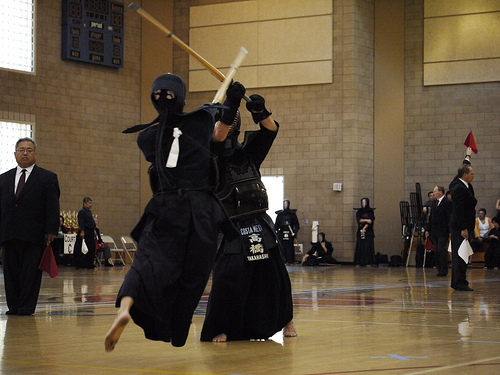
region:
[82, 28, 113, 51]
scoreboard on the wall.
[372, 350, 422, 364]
blue tape on the floor.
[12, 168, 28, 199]
tie on man's chest.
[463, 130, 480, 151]
red flag in man's hand.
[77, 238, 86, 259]
white flag in man's hand.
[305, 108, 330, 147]
wall made of blocks.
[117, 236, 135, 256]
chair on the floor.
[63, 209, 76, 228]
trophies on a table.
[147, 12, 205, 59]
staff in man's hand.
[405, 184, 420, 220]
metal gates near bleachers.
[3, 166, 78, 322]
the suit is black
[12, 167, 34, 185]
the shirt is white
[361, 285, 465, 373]
the floor is shiny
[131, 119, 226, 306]
the attire is black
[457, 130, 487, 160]
the clothe is red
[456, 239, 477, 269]
the clothe is white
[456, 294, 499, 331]
reflection is on the floor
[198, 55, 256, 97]
the swords are wooden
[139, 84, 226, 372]
the gloves are black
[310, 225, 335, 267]
the man is sitting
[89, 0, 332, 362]
two people in a martial arts fight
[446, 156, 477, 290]
a man holding a white cloth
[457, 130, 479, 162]
a hand holding a red cloth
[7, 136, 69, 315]
a man wearing a black suit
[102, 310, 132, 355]
a bare dirty foot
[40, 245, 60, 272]
a red cloth in a hand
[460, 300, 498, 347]
a reflection on the shiny floor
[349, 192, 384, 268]
a competitor waiting his turn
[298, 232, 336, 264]
a martial arts performer sitting on the floor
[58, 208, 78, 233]
golden trophies on a table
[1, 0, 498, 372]
people in a gym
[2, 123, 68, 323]
man wearing black suit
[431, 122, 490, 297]
man holding up a red hanky on left hand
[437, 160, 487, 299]
man holding a white hanky on right hand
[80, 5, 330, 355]
two men are fighting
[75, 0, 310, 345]
men are holding bats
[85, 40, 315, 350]
man wearing black uniforms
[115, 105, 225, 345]
a black tunica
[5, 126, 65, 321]
man wears a white shirt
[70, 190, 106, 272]
man holding a white hanky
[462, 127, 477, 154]
a raised red cloth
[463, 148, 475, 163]
black band of a wrist watch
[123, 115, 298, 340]
fighters wear long black robes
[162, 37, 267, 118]
sticks used for martial art of stick fighting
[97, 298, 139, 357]
a bare foot under robe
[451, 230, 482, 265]
a lowered white cloth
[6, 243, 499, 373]
a shining gym floor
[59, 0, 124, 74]
a black score board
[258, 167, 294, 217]
an open door on far wall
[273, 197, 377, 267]
other participants waiting their turn